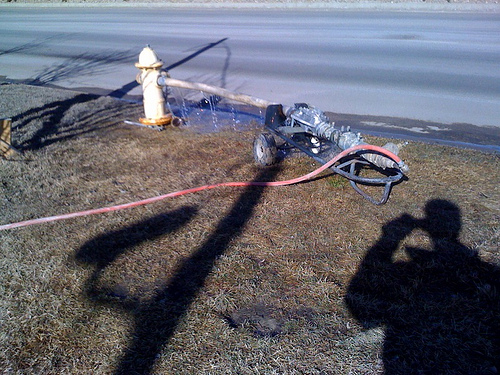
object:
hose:
[0, 143, 402, 229]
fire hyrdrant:
[133, 44, 186, 131]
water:
[166, 102, 498, 154]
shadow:
[0, 35, 71, 54]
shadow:
[0, 45, 141, 86]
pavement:
[0, 0, 499, 152]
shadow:
[344, 196, 500, 374]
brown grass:
[0, 74, 499, 373]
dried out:
[1, 82, 498, 374]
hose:
[157, 77, 290, 117]